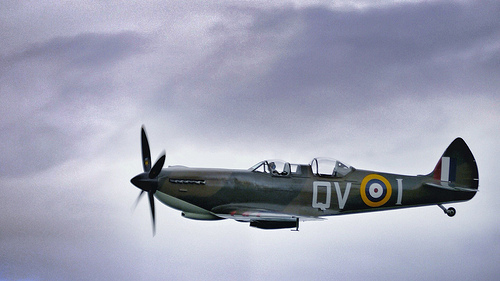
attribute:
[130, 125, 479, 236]
plane — gray, in air, dark green, olive drab, old style, in flight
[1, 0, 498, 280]
sky — cloudy, dark, blue, gray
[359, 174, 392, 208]
bullseye — yellow, britishroyalairforce, white, blue, red, gray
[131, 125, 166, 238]
propeller — large, four-bladed, black, gray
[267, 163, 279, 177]
pilot — wearing head gear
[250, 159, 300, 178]
cockpit — main, empty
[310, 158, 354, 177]
cockpit — second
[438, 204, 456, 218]
landing gear — on back, peaking from bottom, rear, gray, black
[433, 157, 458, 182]
stripes — red, blue, white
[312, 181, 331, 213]
q — large, white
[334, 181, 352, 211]
v — large, white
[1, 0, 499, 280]
clouds — white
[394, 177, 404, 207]
i — white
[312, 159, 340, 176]
cover — glass